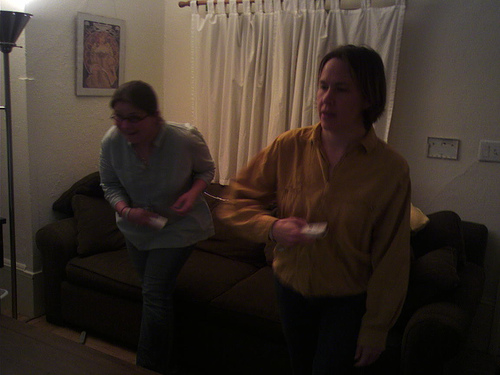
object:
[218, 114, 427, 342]
shirt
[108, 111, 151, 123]
glasses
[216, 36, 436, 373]
man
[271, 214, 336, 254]
controller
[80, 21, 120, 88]
artwork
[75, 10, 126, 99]
matting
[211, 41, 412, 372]
woman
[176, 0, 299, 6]
rod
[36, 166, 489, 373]
cushion couch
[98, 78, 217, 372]
woman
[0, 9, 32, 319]
floor lamp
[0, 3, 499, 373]
living room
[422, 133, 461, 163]
plaque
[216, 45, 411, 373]
man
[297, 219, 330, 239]
game controller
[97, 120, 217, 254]
t shirt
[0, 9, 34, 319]
lamp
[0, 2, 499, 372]
room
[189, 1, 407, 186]
curtain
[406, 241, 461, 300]
pillow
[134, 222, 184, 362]
foot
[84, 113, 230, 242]
shirt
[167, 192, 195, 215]
hand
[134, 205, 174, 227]
controller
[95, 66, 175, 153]
face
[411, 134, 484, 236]
switch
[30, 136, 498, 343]
couch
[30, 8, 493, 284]
wall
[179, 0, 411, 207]
curtains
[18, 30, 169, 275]
wall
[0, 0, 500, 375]
building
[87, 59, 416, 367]
couple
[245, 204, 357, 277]
remote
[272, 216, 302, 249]
hand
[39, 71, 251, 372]
lady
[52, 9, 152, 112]
picture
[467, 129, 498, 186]
light switch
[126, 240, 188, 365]
jeans